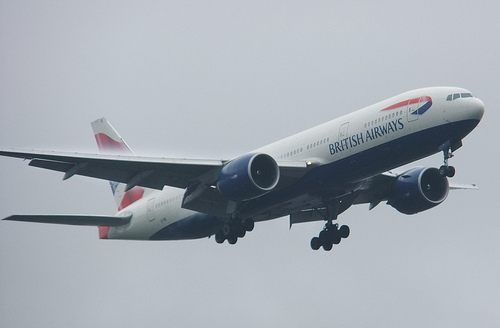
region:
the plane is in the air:
[0, 65, 480, 291]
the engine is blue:
[200, 145, 285, 211]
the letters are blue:
[317, 110, 412, 160]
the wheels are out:
[200, 207, 350, 257]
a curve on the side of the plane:
[367, 82, 444, 128]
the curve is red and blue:
[370, 90, 442, 132]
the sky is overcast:
[25, 7, 310, 107]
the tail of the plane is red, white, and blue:
[50, 90, 150, 202]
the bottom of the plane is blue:
[281, 115, 466, 175]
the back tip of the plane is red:
[80, 210, 121, 245]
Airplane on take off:
[46, 57, 478, 214]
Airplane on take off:
[92, 84, 407, 264]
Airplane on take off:
[169, 69, 497, 290]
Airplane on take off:
[183, 94, 486, 167]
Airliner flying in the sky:
[21, 42, 485, 261]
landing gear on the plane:
[301, 227, 363, 246]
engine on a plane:
[213, 136, 276, 197]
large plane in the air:
[0, 64, 495, 258]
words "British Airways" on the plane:
[323, 116, 406, 155]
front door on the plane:
[404, 94, 421, 126]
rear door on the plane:
[143, 196, 158, 224]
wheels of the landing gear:
[208, 213, 354, 255]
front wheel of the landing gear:
[440, 160, 458, 180]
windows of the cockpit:
[445, 90, 478, 105]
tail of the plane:
[87, 113, 162, 210]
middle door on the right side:
[337, 122, 350, 147]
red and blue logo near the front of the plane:
[377, 98, 432, 119]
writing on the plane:
[326, 124, 399, 145]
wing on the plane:
[12, 144, 79, 176]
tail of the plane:
[85, 120, 126, 135]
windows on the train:
[301, 139, 336, 154]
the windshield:
[452, 90, 470, 101]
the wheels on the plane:
[305, 229, 346, 256]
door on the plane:
[404, 96, 424, 121]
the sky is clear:
[174, 42, 269, 91]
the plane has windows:
[358, 113, 395, 129]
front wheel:
[441, 164, 457, 181]